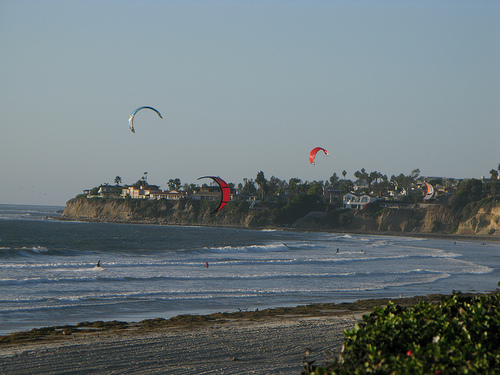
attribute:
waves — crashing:
[233, 237, 492, 286]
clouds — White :
[401, 47, 469, 92]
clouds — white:
[313, 78, 423, 148]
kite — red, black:
[200, 177, 231, 217]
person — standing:
[89, 252, 109, 274]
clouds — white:
[398, 95, 428, 129]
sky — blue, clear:
[0, 2, 498, 209]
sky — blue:
[245, 32, 367, 94]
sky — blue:
[39, 45, 494, 149]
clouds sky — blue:
[299, 62, 410, 126]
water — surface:
[0, 217, 498, 334]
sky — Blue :
[1, 0, 498, 237]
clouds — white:
[363, 58, 447, 118]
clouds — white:
[390, 13, 462, 84]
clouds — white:
[338, 54, 423, 109]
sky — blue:
[2, 24, 499, 173]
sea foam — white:
[201, 240, 291, 250]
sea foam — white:
[3, 257, 119, 276]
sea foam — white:
[259, 227, 279, 236]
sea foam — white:
[4, 272, 459, 304]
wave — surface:
[178, 242, 322, 254]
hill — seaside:
[62, 172, 498, 236]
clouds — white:
[15, 88, 437, 188]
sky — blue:
[5, 2, 497, 166]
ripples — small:
[21, 210, 476, 332]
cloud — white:
[14, 26, 45, 62]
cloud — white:
[362, 102, 459, 146]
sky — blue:
[46, 23, 482, 167]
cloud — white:
[358, 111, 457, 161]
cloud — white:
[357, 119, 475, 170]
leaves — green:
[362, 314, 484, 346]